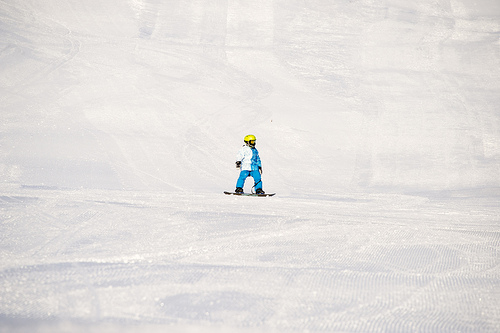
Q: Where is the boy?
A: A mountain.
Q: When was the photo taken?
A: Day time.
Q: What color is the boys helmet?
A: Yellow.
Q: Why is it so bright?
A: Day time.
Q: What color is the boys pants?
A: Blue.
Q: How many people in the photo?
A: One.